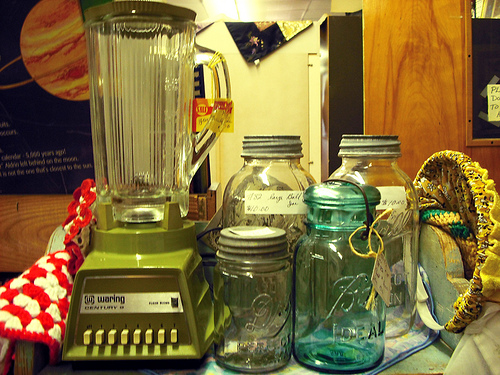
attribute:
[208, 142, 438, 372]
jars — four, empty, glass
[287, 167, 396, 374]
jar — medium, covered, blue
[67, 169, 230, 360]
base — green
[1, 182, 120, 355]
clothing — red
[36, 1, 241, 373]
blender — old, green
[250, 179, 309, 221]
stickers — silver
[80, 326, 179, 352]
buttons — white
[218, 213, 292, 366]
jar — glass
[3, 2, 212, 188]
poster — black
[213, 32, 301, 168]
wall — white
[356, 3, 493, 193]
door — wooden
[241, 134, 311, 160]
top — metal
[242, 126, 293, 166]
latch — white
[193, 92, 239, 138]
tag — red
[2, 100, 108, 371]
mitt — red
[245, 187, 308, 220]
tag — white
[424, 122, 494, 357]
napkin holder — wood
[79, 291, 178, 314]
label — silver